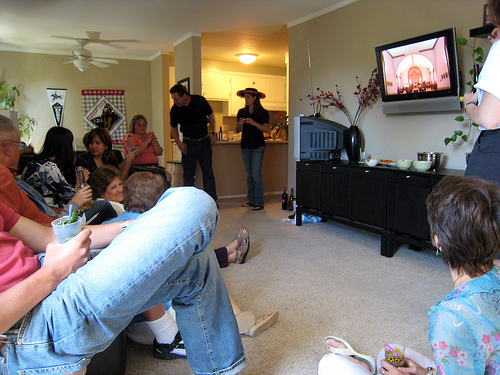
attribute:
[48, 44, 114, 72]
ceiling fan — white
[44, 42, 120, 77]
ceiling — white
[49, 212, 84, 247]
cup — plastic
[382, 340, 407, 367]
cup — clear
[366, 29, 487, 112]
television — thin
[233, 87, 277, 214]
friend — girl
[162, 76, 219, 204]
friend — man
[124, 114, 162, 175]
friend — female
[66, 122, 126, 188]
friend — female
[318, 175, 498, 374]
friend — female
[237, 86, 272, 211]
woman — caucasian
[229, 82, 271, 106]
hat — thin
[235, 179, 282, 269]
sandals — beige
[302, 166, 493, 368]
woman — caucasian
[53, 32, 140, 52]
fan shadow — dark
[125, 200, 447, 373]
ivory rugs — beige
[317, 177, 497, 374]
woman — caucasian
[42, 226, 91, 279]
hand — man's 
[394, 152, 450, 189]
bowls — white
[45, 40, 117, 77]
fan — white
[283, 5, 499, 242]
wall — beige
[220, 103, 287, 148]
shirt — dark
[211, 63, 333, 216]
woman — caucasian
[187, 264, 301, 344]
sandal — black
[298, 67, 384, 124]
flowers — red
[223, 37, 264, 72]
ceiling light — white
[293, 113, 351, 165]
tv — grey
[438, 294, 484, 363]
pattern — flower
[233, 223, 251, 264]
sandals — beige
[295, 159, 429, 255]
cabinet — black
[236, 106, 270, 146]
shirt — black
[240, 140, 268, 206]
pants — jeans